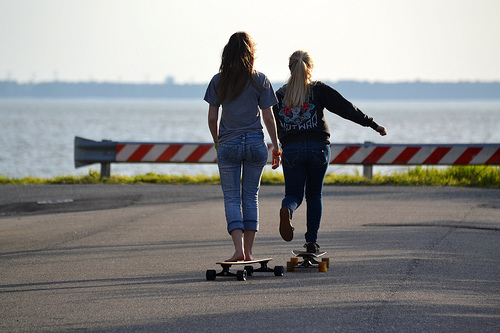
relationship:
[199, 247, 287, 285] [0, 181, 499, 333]
skateboard on ground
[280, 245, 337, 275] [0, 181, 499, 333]
skateboard on ground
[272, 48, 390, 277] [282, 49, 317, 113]
woman has ponytail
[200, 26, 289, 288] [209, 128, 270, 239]
woman wearing jeans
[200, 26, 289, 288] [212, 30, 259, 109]
woman has hair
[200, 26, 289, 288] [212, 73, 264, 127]
woman has back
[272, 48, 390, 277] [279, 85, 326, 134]
woman has back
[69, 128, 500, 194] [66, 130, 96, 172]
guardrail has end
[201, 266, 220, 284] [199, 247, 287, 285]
wheel under skateboard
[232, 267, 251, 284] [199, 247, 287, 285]
wheel under skateboard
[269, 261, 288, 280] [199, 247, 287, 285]
wheel under skateboard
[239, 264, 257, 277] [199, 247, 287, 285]
wheel under skateboard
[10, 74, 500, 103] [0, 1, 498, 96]
land in horizon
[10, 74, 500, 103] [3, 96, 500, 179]
land beyond water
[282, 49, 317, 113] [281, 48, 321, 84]
ponytail on head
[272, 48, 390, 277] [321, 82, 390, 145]
woman has arm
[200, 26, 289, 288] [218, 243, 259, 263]
woman has feet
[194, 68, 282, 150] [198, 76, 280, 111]
tee shirt has sleeves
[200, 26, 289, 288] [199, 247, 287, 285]
woman on skateboard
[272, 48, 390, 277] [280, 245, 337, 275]
woman on skateboard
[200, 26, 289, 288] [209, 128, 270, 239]
woman has jeans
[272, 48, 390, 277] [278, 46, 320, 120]
woman has hair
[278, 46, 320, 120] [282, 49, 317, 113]
hair in ponytail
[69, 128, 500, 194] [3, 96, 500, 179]
guardrail by water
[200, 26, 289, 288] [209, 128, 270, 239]
woman in jeans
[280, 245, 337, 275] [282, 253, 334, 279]
skateboard has wheels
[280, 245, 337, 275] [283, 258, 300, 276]
skateboard has wheel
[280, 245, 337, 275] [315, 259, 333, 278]
skateboard has wheel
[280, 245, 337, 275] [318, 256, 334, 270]
skateboard has wheel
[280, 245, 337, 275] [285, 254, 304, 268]
skateboard has wheel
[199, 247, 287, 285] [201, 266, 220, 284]
skateboard has wheel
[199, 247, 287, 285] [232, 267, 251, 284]
skateboard has wheel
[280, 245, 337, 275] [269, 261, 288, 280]
skateboard has wheel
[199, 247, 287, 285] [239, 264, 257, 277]
skateboard has wheel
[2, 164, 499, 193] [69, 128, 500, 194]
grass behind guardrail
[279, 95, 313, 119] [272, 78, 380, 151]
face on back of shirt